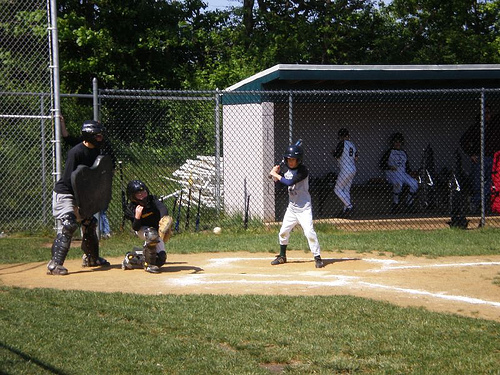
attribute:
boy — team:
[272, 141, 331, 273]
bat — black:
[268, 140, 302, 180]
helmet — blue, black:
[285, 146, 306, 162]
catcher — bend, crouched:
[124, 183, 178, 272]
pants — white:
[280, 209, 322, 257]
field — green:
[9, 234, 497, 375]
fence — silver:
[7, 91, 498, 239]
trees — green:
[9, 5, 495, 61]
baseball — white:
[210, 226, 226, 236]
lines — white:
[360, 276, 500, 318]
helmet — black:
[77, 113, 107, 141]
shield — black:
[67, 157, 122, 219]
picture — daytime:
[5, 6, 495, 315]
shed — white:
[217, 95, 279, 225]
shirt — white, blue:
[281, 170, 320, 212]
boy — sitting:
[389, 133, 420, 206]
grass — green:
[9, 289, 476, 375]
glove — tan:
[154, 213, 177, 242]